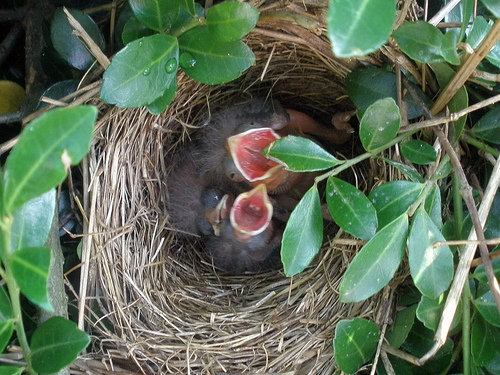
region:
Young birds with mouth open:
[170, 87, 340, 269]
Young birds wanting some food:
[170, 90, 345, 260]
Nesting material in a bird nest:
[90, 185, 185, 311]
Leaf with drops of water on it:
[95, 25, 180, 111]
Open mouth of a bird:
[225, 180, 277, 239]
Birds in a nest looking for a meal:
[150, 70, 355, 300]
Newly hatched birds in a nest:
[171, 86, 361, 286]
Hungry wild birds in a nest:
[160, 85, 345, 280]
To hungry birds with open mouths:
[221, 110, 283, 240]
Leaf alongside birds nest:
[313, 308, 397, 373]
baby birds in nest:
[172, 101, 334, 259]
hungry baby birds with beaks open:
[181, 109, 329, 261]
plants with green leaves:
[400, 105, 494, 366]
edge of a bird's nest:
[88, 248, 440, 369]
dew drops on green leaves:
[90, 3, 262, 118]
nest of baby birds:
[71, 16, 423, 366]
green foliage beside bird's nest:
[8, 65, 157, 372]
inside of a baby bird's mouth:
[215, 118, 303, 191]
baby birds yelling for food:
[102, 48, 410, 348]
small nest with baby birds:
[59, 33, 429, 371]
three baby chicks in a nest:
[103, 10, 433, 367]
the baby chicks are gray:
[167, 115, 337, 310]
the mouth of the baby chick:
[206, 120, 296, 190]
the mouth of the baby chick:
[220, 180, 295, 242]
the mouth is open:
[225, 181, 290, 242]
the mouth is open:
[225, 127, 305, 182]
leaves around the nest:
[316, 1, 493, 367]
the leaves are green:
[320, 17, 465, 367]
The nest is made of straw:
[66, 17, 466, 372]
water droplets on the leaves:
[151, 52, 204, 77]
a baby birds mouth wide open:
[230, 183, 270, 234]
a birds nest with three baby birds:
[0, 0, 499, 374]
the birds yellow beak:
[210, 190, 226, 225]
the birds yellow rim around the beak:
[231, 183, 273, 235]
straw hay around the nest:
[88, 112, 202, 374]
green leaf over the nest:
[326, 174, 379, 239]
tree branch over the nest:
[263, 94, 498, 374]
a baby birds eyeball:
[197, 182, 217, 208]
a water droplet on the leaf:
[164, 55, 178, 74]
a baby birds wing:
[158, 133, 202, 233]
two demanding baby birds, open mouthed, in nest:
[218, 118, 293, 245]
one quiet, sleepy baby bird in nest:
[146, 163, 241, 250]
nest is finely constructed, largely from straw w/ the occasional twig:
[87, 0, 402, 374]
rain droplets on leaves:
[132, 31, 200, 89]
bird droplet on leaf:
[408, 210, 457, 300]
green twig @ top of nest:
[249, 7, 323, 32]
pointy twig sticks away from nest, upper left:
[58, 4, 122, 83]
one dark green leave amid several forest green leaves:
[336, 62, 431, 124]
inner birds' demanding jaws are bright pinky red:
[223, 126, 293, 243]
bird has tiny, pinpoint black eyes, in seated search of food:
[221, 116, 260, 185]